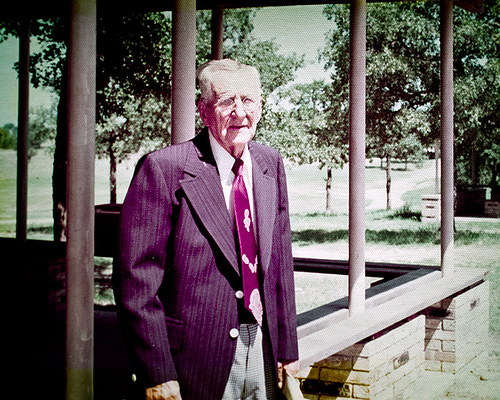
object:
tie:
[227, 159, 268, 326]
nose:
[228, 96, 245, 121]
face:
[213, 70, 259, 147]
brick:
[425, 326, 462, 341]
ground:
[434, 114, 459, 132]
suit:
[108, 124, 304, 390]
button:
[230, 287, 245, 302]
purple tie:
[228, 156, 263, 332]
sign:
[421, 192, 438, 227]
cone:
[246, 284, 272, 331]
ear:
[193, 93, 211, 129]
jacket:
[115, 127, 300, 397]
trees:
[306, 0, 498, 182]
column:
[64, 2, 94, 399]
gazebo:
[1, 0, 489, 398]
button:
[227, 324, 238, 344]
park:
[0, 0, 498, 400]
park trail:
[297, 15, 485, 279]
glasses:
[202, 83, 265, 117]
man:
[111, 57, 305, 396]